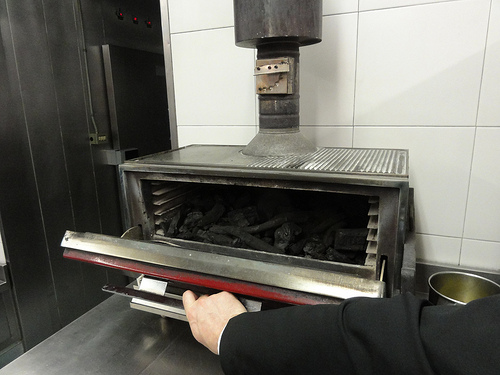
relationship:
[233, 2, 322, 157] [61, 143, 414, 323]
pipe on stove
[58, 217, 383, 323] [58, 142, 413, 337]
door on heater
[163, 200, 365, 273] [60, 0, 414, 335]
charcoal in bowl heater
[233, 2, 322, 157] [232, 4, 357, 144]
pipe on heater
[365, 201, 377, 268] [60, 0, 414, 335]
racks are in bowl heater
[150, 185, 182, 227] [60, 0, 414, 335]
racks are in bowl heater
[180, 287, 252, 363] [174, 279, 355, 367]
hand on arm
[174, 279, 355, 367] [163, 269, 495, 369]
arm on man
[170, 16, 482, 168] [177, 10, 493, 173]
white tiles are on wall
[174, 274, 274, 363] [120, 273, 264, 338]
hand on handle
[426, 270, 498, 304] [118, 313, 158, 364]
bowl on ground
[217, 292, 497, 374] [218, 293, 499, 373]
sleeve on arm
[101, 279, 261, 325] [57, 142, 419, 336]
handle on oven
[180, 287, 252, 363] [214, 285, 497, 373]
hand of man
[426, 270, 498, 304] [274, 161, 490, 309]
bowl by bowl heater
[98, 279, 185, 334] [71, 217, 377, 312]
handle of door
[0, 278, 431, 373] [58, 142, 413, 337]
counter top below heater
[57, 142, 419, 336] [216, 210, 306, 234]
oven with charcoal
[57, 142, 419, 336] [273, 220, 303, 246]
oven with charcoal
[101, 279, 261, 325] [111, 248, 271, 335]
handle on cooker